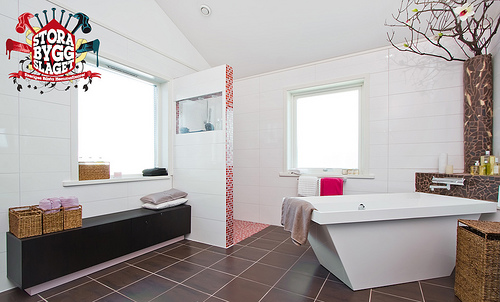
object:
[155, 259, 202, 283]
tile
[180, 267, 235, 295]
tile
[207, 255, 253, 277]
tile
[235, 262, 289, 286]
tile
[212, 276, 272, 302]
tile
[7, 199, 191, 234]
shelf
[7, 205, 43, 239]
basket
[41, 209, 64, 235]
basket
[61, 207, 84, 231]
basket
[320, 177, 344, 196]
towel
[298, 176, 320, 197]
towel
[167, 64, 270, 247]
shower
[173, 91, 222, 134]
window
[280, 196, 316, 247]
towel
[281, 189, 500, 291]
tub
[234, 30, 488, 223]
wall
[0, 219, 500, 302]
floor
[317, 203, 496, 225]
edge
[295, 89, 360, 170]
window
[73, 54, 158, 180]
window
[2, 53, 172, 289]
wall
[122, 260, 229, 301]
line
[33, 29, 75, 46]
words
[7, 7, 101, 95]
graphic image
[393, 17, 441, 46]
branches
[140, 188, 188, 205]
cushion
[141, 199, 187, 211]
cushion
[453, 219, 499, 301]
hamper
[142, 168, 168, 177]
towels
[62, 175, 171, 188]
window sill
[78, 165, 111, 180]
basket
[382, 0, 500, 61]
plant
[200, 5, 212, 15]
light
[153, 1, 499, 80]
ceiling